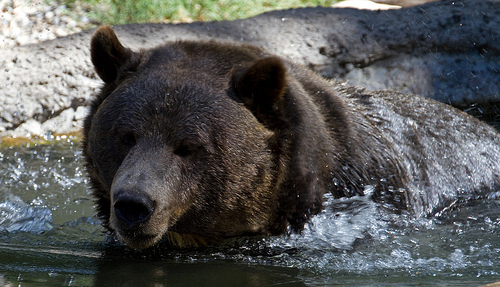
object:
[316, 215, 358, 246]
water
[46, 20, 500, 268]
bear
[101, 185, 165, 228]
nose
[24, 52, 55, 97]
sunlight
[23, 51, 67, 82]
rocks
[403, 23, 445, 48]
rocks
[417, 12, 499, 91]
shadow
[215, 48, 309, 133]
ear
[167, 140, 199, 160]
eye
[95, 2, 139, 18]
grass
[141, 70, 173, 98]
fur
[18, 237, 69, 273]
log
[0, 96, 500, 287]
river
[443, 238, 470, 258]
drops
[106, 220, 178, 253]
mouth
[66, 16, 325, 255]
head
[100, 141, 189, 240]
snout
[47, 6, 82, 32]
ground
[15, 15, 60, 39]
side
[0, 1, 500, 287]
picture